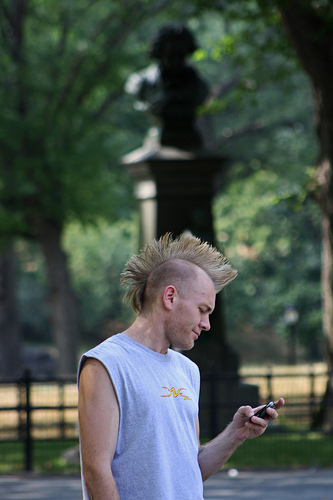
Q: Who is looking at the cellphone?
A: The man.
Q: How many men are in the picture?
A: One.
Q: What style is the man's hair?
A: Mohawk.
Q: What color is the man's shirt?
A: Grey and yellow.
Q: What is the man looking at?
A: A cell phone.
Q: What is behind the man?
A: A statue.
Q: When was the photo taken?
A: Daytime.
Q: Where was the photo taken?
A: In a park.